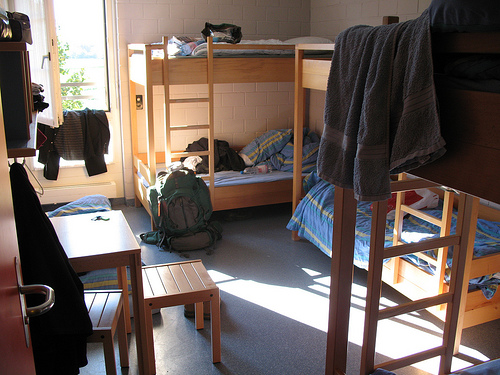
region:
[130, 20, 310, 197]
a bunck bed made of wood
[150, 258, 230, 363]
a backless wooden chair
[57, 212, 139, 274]
the surface of a wooden table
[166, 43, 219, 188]
the ladder of a bunk bed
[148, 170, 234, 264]
a green pack propped against a bunk bed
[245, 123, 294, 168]
blue and yellow pillow cases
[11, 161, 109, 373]
a black jacket hanging from a door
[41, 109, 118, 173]
a jacket laying on a windowsill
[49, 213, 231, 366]
a wood table and two chairs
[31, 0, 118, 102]
an open window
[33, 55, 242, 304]
shirts hung near window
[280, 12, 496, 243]
a towel hanging on a bed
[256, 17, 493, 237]
grey towel hanging on a bunk bed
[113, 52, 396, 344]
bunk beds together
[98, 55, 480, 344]
wooden bunk beds together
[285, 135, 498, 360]
the ladder to a wooden bunk bed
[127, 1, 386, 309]
unmade bed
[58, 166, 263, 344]
an empty table with chairs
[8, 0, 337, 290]
an open window with clothes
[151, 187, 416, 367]
a backpack against a bed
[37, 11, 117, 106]
open window in room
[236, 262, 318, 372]
gray flooring in room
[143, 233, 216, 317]
brown chair in room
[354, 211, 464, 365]
ladder to bunk bed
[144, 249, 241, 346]
four legs of chair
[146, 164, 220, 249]
back pack next to bed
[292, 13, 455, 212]
towel hanging off of bed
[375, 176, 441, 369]
four steps of ladder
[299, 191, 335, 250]
blue sheet on bed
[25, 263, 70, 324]
silver door handle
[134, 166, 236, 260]
a bookbag laying against the ladder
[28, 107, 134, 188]
clothes hanging out the window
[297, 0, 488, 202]
towels hanging from the bunk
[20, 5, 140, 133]
the window is open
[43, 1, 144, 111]
light coming in from the window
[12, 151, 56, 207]
a white clothes hanger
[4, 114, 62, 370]
the door is open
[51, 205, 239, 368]
table with stools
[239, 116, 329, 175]
pillow on the bunk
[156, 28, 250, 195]
ladder of the bunk bed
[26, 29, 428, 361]
picture is taken indoors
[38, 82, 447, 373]
the room is messy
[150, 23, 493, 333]
Bunk beds in the room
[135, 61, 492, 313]
the beds are made of wood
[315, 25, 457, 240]
a towel is on a bed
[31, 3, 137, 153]
picture taken during the day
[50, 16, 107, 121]
the sun is shining outside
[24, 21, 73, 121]
the window is open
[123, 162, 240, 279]
a backpack on the floor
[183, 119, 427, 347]
stairs up against the beds